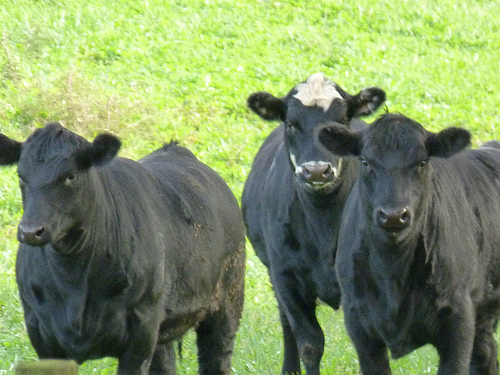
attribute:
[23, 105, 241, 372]
cow — black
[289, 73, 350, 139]
black and white — cow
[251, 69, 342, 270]
cow — black, middle